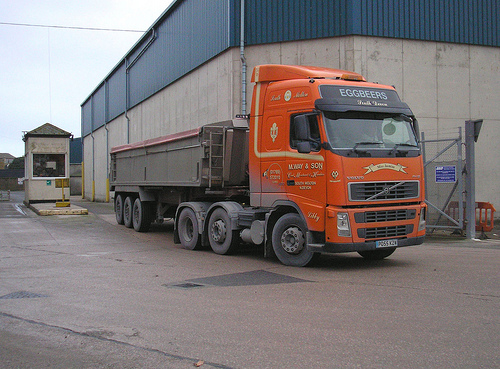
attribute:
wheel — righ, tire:
[266, 211, 318, 270]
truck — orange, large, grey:
[103, 58, 436, 270]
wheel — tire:
[359, 235, 397, 264]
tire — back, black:
[111, 195, 128, 226]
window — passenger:
[287, 112, 320, 157]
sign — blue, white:
[431, 162, 457, 188]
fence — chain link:
[415, 127, 467, 245]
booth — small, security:
[18, 118, 74, 207]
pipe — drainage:
[237, 1, 252, 122]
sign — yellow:
[52, 175, 72, 193]